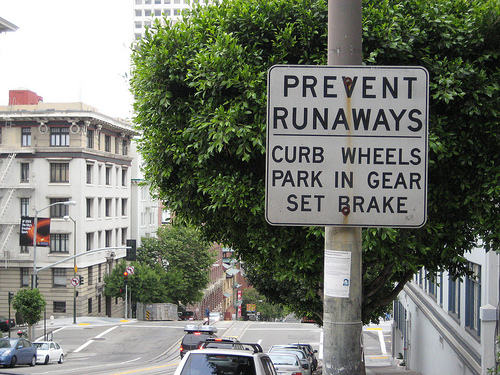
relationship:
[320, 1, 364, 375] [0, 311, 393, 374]
pole near street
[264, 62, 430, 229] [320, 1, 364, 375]
sign on pole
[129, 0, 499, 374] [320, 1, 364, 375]
tree near pole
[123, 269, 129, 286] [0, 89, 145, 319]
traffic signal near building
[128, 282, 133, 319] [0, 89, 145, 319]
pole near building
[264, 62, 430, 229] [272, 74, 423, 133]
sign says prevent runaways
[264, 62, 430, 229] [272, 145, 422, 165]
sign says curb wheels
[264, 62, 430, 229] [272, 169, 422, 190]
sign says park in gear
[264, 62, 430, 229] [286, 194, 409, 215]
sign says set brake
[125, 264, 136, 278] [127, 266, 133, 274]
sign signifies no left turn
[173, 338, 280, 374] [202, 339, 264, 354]
vehicle has luggage rack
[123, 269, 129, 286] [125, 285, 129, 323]
traffic signal on pole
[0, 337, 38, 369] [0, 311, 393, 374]
vehicle on street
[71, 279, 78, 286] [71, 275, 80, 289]
no left turn on sign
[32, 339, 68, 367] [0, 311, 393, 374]
car on street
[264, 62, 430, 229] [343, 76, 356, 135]
sign has rust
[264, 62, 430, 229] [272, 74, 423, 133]
sign to prevent runaway cars